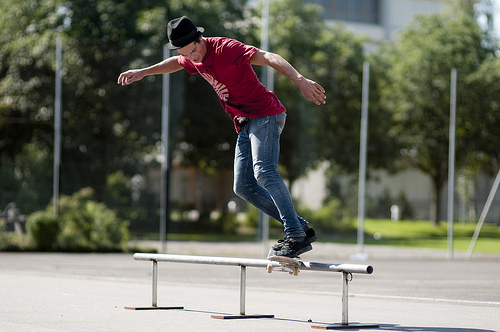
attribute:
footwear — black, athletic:
[266, 227, 318, 260]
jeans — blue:
[233, 129, 292, 204]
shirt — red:
[199, 50, 282, 140]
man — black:
[116, 14, 327, 258]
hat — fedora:
[163, 14, 204, 50]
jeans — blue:
[232, 107, 312, 240]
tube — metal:
[130, 237, 398, 291]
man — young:
[107, 14, 344, 265]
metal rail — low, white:
[130, 239, 375, 281]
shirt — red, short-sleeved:
[170, 38, 287, 130]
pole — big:
[339, 270, 351, 325]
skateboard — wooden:
[267, 244, 307, 274]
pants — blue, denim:
[211, 97, 351, 264]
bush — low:
[25, 184, 130, 253]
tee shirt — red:
[172, 34, 287, 134]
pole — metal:
[446, 65, 458, 261]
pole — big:
[238, 262, 248, 317]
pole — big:
[131, 250, 372, 274]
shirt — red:
[184, 38, 286, 122]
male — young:
[143, 8, 344, 223]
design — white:
[203, 73, 235, 105]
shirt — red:
[117, 17, 343, 256]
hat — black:
[164, 15, 203, 48]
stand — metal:
[332, 266, 362, 322]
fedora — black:
[161, 8, 206, 54]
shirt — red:
[156, 25, 294, 160]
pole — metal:
[205, 249, 276, 269]